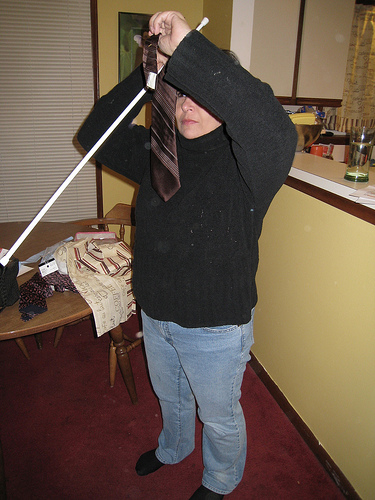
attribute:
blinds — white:
[0, 0, 98, 228]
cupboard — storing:
[252, 2, 351, 110]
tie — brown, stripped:
[144, 50, 191, 204]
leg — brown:
[109, 322, 138, 403]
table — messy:
[0, 215, 131, 344]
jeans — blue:
[137, 305, 251, 491]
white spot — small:
[311, 432, 332, 452]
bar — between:
[267, 149, 370, 208]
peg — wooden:
[95, 312, 160, 407]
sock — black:
[135, 446, 163, 476]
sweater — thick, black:
[55, 30, 302, 331]